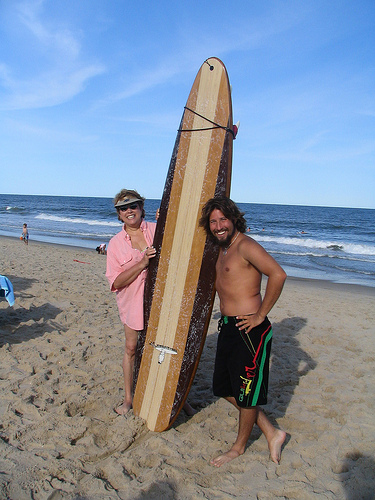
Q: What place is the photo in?
A: It is at the beach.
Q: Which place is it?
A: It is a beach.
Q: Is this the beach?
A: Yes, it is the beach.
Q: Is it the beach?
A: Yes, it is the beach.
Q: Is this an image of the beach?
A: Yes, it is showing the beach.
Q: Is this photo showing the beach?
A: Yes, it is showing the beach.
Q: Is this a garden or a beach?
A: It is a beach.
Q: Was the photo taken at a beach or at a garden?
A: It was taken at a beach.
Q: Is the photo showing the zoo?
A: No, the picture is showing the beach.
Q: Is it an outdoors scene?
A: Yes, it is outdoors.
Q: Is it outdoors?
A: Yes, it is outdoors.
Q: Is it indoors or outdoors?
A: It is outdoors.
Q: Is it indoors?
A: No, it is outdoors.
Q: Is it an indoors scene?
A: No, it is outdoors.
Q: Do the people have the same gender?
A: No, they are both male and female.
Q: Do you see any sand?
A: Yes, there is sand.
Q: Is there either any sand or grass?
A: Yes, there is sand.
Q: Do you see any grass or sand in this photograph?
A: Yes, there is sand.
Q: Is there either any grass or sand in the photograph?
A: Yes, there is sand.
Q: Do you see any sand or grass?
A: Yes, there is sand.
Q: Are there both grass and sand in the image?
A: No, there is sand but no grass.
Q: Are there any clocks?
A: No, there are no clocks.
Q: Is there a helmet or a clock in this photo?
A: No, there are no clocks or helmets.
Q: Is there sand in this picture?
A: Yes, there is sand.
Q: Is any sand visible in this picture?
A: Yes, there is sand.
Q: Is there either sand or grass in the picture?
A: Yes, there is sand.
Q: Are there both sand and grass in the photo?
A: No, there is sand but no grass.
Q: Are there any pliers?
A: No, there are no pliers.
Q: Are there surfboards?
A: Yes, there is a surfboard.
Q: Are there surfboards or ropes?
A: Yes, there is a surfboard.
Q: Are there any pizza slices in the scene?
A: No, there are no pizza slices.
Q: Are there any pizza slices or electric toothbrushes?
A: No, there are no pizza slices or electric toothbrushes.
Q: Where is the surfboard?
A: The surfboard is in the sand.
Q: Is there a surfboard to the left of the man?
A: Yes, there is a surfboard to the left of the man.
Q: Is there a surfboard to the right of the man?
A: No, the surfboard is to the left of the man.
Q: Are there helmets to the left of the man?
A: No, there is a surfboard to the left of the man.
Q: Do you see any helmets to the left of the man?
A: No, there is a surfboard to the left of the man.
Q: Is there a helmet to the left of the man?
A: No, there is a surfboard to the left of the man.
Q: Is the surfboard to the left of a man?
A: Yes, the surfboard is to the left of a man.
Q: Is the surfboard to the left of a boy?
A: No, the surfboard is to the left of a man.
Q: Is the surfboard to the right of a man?
A: No, the surfboard is to the left of a man.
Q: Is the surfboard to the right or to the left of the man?
A: The surfboard is to the left of the man.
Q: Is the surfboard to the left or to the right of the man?
A: The surfboard is to the left of the man.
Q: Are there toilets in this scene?
A: No, there are no toilets.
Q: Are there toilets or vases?
A: No, there are no toilets or vases.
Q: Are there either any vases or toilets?
A: No, there are no toilets or vases.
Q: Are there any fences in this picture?
A: No, there are no fences.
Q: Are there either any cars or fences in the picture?
A: No, there are no fences or cars.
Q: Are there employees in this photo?
A: No, there are no employees.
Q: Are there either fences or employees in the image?
A: No, there are no employees or fences.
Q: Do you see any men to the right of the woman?
A: Yes, there is a man to the right of the woman.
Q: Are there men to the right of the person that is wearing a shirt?
A: Yes, there is a man to the right of the woman.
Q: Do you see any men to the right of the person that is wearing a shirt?
A: Yes, there is a man to the right of the woman.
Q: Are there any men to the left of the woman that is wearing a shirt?
A: No, the man is to the right of the woman.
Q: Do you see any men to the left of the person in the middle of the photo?
A: No, the man is to the right of the woman.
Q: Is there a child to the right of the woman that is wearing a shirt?
A: No, there is a man to the right of the woman.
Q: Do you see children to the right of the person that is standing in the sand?
A: No, there is a man to the right of the woman.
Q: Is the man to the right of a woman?
A: Yes, the man is to the right of a woman.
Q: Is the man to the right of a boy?
A: No, the man is to the right of a woman.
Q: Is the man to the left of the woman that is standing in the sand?
A: No, the man is to the right of the woman.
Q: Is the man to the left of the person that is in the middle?
A: No, the man is to the right of the woman.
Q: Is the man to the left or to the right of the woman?
A: The man is to the right of the woman.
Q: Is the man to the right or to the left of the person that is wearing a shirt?
A: The man is to the right of the woman.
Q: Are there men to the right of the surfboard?
A: Yes, there is a man to the right of the surfboard.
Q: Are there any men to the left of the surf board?
A: No, the man is to the right of the surf board.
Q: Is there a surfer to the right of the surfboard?
A: No, there is a man to the right of the surfboard.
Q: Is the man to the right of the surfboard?
A: Yes, the man is to the right of the surfboard.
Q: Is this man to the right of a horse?
A: No, the man is to the right of the surfboard.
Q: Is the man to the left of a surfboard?
A: No, the man is to the right of a surfboard.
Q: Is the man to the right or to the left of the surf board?
A: The man is to the right of the surf board.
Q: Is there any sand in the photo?
A: Yes, there is sand.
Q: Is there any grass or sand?
A: Yes, there is sand.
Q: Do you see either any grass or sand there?
A: Yes, there is sand.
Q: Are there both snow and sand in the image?
A: No, there is sand but no snow.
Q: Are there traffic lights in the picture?
A: No, there are no traffic lights.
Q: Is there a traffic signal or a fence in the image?
A: No, there are no traffic lights or fences.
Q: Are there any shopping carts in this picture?
A: No, there are no shopping carts.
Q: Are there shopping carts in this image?
A: No, there are no shopping carts.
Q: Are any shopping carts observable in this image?
A: No, there are no shopping carts.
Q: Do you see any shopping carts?
A: No, there are no shopping carts.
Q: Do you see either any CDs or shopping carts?
A: No, there are no shopping carts or cds.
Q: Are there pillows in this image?
A: No, there are no pillows.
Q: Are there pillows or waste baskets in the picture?
A: No, there are no pillows or waste baskets.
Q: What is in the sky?
A: The clouds are in the sky.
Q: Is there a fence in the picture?
A: No, there are no fences.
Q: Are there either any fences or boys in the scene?
A: No, there are no fences or boys.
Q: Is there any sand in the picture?
A: Yes, there is sand.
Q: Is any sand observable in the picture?
A: Yes, there is sand.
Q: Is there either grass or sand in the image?
A: Yes, there is sand.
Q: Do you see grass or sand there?
A: Yes, there is sand.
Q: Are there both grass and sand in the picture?
A: No, there is sand but no grass.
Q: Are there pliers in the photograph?
A: No, there are no pliers.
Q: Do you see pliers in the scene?
A: No, there are no pliers.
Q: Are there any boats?
A: No, there are no boats.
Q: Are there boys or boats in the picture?
A: No, there are no boats or boys.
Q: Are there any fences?
A: No, there are no fences.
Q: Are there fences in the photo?
A: No, there are no fences.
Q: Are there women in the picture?
A: Yes, there is a woman.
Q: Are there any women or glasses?
A: Yes, there is a woman.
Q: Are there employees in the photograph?
A: No, there are no employees.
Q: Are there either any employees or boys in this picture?
A: No, there are no employees or boys.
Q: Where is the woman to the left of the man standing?
A: The woman is standing in the sand.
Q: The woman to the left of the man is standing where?
A: The woman is standing in the sand.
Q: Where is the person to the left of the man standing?
A: The woman is standing in the sand.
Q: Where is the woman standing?
A: The woman is standing in the sand.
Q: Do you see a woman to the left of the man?
A: Yes, there is a woman to the left of the man.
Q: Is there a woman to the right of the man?
A: No, the woman is to the left of the man.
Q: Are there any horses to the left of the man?
A: No, there is a woman to the left of the man.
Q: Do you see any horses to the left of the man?
A: No, there is a woman to the left of the man.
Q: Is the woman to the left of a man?
A: Yes, the woman is to the left of a man.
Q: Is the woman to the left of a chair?
A: No, the woman is to the left of a man.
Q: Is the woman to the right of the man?
A: No, the woman is to the left of the man.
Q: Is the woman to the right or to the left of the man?
A: The woman is to the left of the man.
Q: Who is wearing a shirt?
A: The woman is wearing a shirt.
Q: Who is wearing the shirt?
A: The woman is wearing a shirt.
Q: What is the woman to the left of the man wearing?
A: The woman is wearing a shirt.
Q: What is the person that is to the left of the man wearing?
A: The woman is wearing a shirt.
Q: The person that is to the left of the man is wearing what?
A: The woman is wearing a shirt.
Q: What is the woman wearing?
A: The woman is wearing a shirt.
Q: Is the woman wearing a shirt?
A: Yes, the woman is wearing a shirt.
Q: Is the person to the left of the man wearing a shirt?
A: Yes, the woman is wearing a shirt.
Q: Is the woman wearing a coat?
A: No, the woman is wearing a shirt.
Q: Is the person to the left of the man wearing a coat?
A: No, the woman is wearing a shirt.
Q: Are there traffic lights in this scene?
A: No, there are no traffic lights.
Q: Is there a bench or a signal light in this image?
A: No, there are no traffic lights or benches.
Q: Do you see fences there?
A: No, there are no fences.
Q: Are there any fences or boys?
A: No, there are no fences or boys.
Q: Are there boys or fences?
A: No, there are no fences or boys.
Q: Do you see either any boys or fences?
A: No, there are no fences or boys.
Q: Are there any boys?
A: No, there are no boys.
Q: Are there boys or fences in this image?
A: No, there are no boys or fences.